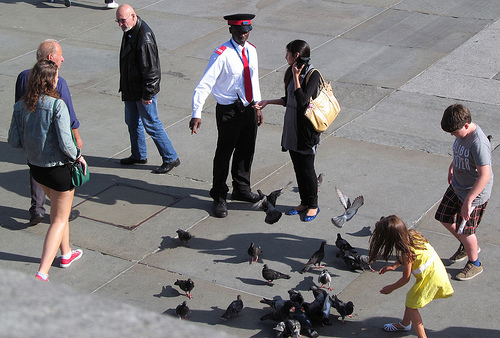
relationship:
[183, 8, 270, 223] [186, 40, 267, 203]
man wearing uniform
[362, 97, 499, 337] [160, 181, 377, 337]
children playing with birds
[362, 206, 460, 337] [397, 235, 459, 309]
girl in yellow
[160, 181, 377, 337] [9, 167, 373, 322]
birds are on pavement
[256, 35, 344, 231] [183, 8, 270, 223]
woman standing by men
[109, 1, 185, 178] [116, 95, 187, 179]
person has legs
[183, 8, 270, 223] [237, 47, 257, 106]
man has tie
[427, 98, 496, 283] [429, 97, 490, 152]
boy has head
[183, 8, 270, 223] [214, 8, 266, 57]
man has head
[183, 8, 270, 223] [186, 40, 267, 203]
man in uniform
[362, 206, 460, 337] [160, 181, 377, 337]
girl feeding pigeons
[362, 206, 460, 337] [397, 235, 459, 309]
girl in yellow dress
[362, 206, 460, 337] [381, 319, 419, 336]
girl with sandals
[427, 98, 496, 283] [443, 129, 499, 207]
boy in grey shirt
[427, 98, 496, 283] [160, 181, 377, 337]
boy standing next to pigeons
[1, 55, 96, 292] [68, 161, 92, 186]
woman with purse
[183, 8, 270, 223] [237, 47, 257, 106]
man with tie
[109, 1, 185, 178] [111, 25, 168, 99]
man with jacket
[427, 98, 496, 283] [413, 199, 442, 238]
boy looking down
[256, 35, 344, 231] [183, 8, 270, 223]
woman towards man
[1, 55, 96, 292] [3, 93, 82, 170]
woman wearing jacket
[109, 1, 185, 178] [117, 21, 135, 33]
man has facial hair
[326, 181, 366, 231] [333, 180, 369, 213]
birds extending wings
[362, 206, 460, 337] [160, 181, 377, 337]
child feeding pigeons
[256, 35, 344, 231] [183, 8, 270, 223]
woman talking to man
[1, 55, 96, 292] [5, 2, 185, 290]
woman walking around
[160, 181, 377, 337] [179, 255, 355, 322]
flock of birds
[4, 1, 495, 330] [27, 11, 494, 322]
people in city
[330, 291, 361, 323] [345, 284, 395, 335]
pigeons getting food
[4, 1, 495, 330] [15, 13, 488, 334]
people up in daytime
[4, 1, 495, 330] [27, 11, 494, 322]
people enjoying city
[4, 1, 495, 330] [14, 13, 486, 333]
people enjoying day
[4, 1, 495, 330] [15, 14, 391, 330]
people out in sunshine